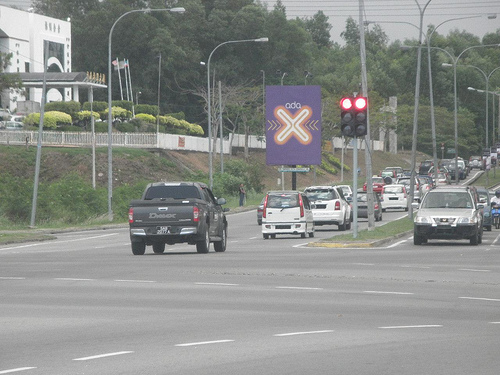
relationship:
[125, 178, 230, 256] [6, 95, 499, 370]
truck driving through intersection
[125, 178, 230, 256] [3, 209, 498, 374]
truck driving through intersection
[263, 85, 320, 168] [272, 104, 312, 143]
billboard with "x"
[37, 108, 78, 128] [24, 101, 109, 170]
bush on hill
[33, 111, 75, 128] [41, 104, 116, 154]
bush on hill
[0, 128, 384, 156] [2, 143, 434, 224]
fence on hill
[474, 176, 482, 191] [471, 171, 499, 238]
person riding motorcycle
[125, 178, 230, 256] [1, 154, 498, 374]
truck going down road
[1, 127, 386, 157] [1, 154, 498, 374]
fence above road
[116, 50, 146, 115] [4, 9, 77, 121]
flags in front of building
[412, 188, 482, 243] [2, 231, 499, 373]
car stopped at intersection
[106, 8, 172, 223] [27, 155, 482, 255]
pole on side of road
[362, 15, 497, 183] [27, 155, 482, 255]
light post on side of road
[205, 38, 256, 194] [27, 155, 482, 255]
pole on side of road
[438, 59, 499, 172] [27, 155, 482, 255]
light post on side of road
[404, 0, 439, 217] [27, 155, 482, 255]
light post on side of road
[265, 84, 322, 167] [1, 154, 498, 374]
sign on side of road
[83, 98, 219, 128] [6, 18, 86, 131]
bushes in front of building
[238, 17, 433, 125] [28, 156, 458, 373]
trees above road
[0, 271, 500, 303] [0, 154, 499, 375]
line in road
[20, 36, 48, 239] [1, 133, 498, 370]
pole in ground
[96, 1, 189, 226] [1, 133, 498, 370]
pole in ground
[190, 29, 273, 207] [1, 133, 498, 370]
pole in ground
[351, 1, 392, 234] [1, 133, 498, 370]
pole in ground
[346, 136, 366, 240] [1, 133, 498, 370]
pole in ground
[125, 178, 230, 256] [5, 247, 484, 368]
truck on street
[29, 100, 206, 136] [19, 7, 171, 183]
hydrangeas on building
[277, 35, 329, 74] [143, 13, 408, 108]
leaves on tree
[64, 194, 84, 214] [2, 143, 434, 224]
grass on hill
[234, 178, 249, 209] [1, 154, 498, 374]
person beside road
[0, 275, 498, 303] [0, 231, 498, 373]
lines on street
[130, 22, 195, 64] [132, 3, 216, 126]
leaves on tree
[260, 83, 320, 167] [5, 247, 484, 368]
sign on street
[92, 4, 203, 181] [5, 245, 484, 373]
street light on ground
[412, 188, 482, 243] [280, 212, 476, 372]
car stopped at intersection